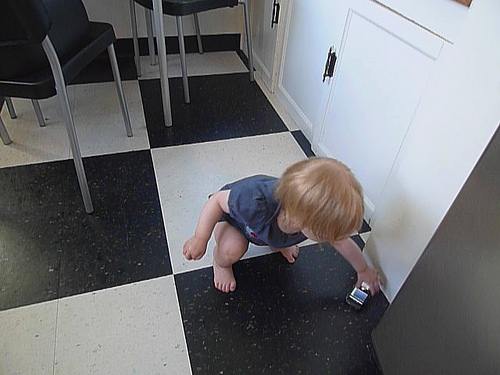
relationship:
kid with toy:
[211, 135, 361, 292] [342, 273, 374, 315]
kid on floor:
[211, 135, 361, 292] [108, 157, 177, 301]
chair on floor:
[15, 16, 148, 198] [108, 157, 177, 301]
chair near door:
[15, 16, 148, 198] [276, 19, 440, 127]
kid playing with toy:
[211, 135, 361, 292] [342, 273, 374, 315]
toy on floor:
[342, 273, 374, 315] [108, 157, 177, 301]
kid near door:
[211, 135, 361, 292] [276, 19, 440, 127]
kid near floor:
[211, 135, 361, 292] [108, 157, 177, 301]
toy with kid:
[342, 273, 374, 315] [211, 135, 361, 292]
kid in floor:
[211, 135, 361, 292] [108, 157, 177, 301]